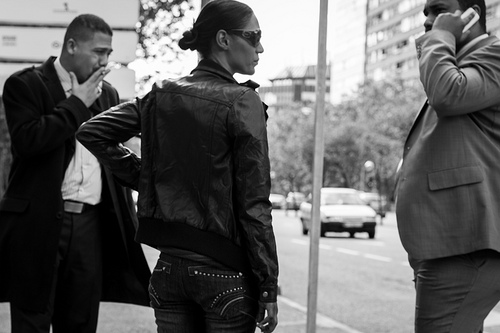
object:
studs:
[193, 270, 198, 275]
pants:
[145, 251, 257, 333]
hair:
[176, 0, 253, 62]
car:
[296, 186, 377, 238]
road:
[269, 209, 500, 333]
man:
[395, 0, 500, 333]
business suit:
[393, 27, 500, 333]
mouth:
[252, 58, 260, 65]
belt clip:
[63, 199, 84, 214]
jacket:
[71, 56, 279, 306]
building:
[358, 0, 500, 206]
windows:
[376, 48, 383, 60]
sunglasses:
[222, 27, 262, 47]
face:
[226, 7, 263, 76]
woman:
[72, 0, 280, 333]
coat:
[0, 55, 156, 333]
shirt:
[51, 54, 104, 207]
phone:
[458, 7, 481, 34]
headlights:
[325, 217, 345, 224]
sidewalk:
[0, 241, 348, 333]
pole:
[303, 0, 329, 333]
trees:
[351, 77, 429, 211]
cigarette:
[101, 71, 106, 76]